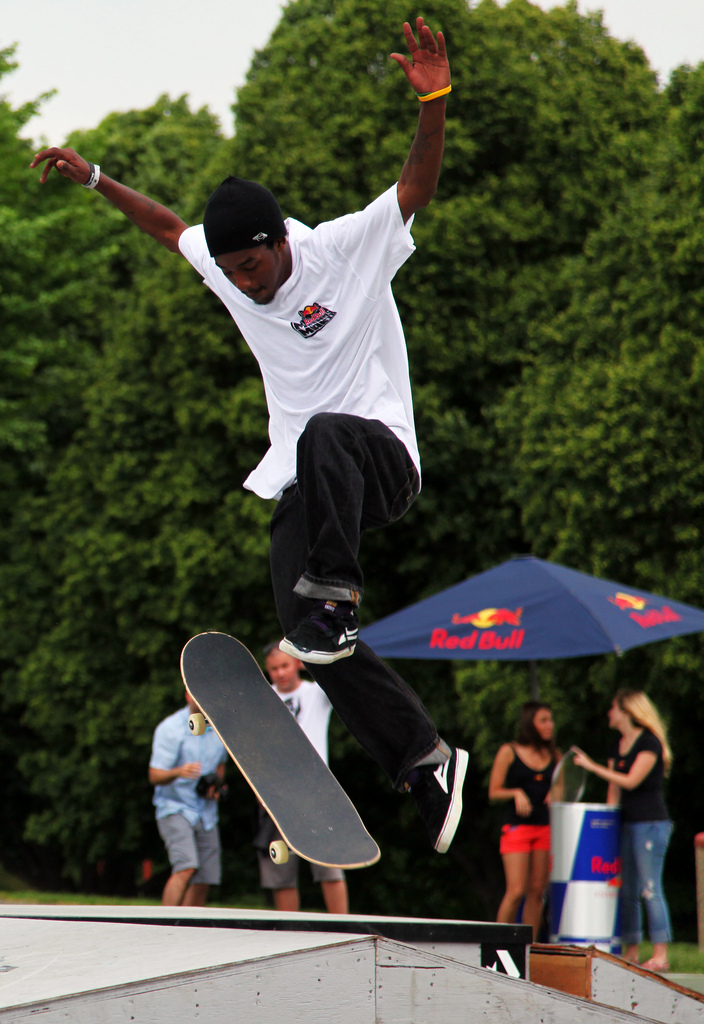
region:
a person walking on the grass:
[593, 689, 688, 982]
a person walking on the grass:
[486, 704, 563, 926]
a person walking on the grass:
[141, 685, 231, 905]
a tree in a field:
[448, 58, 701, 823]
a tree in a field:
[41, 1, 658, 892]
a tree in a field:
[1, 41, 131, 528]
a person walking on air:
[32, 20, 469, 860]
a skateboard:
[179, 625, 393, 877]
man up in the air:
[78, 20, 440, 596]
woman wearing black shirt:
[592, 681, 700, 952]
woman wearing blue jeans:
[608, 686, 687, 942]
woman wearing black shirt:
[495, 688, 570, 916]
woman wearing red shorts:
[494, 685, 571, 941]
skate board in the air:
[178, 654, 308, 901]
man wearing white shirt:
[32, 17, 460, 580]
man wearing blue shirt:
[131, 739, 222, 928]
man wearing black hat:
[51, 9, 481, 537]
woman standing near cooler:
[601, 675, 686, 960]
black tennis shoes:
[280, 595, 358, 662]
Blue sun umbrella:
[332, 549, 698, 667]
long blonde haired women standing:
[571, 687, 672, 969]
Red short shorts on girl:
[495, 823, 551, 853]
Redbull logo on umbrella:
[424, 602, 528, 653]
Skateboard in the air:
[181, 625, 381, 868]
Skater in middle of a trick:
[27, 14, 467, 853]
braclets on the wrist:
[412, 81, 452, 101]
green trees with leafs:
[547, 291, 633, 395]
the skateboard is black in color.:
[172, 629, 386, 872]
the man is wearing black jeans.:
[31, 18, 471, 860]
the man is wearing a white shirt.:
[30, 16, 474, 852]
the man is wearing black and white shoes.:
[29, 17, 470, 856]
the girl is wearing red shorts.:
[490, 700, 564, 921]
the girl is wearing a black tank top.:
[488, 698, 567, 940]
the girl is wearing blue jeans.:
[574, 684, 683, 968]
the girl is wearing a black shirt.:
[571, 692, 680, 967]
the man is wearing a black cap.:
[188, 172, 295, 311]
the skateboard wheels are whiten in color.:
[184, 712, 289, 871]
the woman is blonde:
[591, 684, 702, 981]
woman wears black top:
[470, 689, 582, 980]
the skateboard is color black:
[175, 626, 390, 888]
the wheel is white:
[265, 838, 290, 872]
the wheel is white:
[181, 707, 212, 745]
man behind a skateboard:
[246, 628, 372, 919]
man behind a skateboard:
[131, 648, 256, 908]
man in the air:
[27, 11, 510, 860]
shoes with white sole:
[409, 739, 480, 864]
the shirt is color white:
[161, 177, 444, 505]